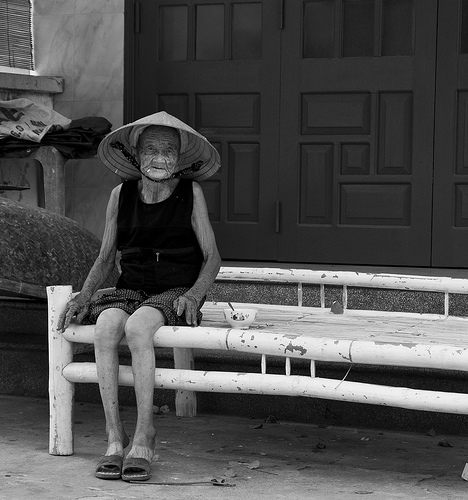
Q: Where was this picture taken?
A: A sidewalk.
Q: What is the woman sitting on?
A: A bench.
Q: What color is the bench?
A: White.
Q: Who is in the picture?
A: A woman.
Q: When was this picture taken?
A: Daytime.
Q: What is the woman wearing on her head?
A: A hat.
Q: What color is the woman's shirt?
A: Black.